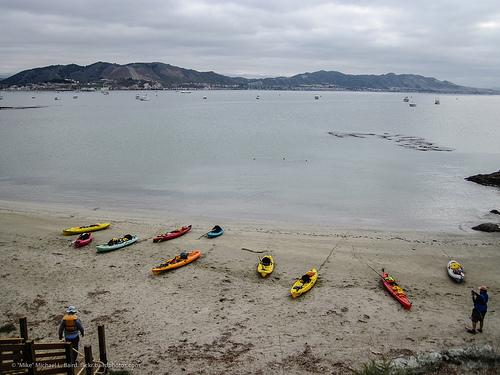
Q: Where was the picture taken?
A: By a body of water.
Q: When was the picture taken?
A: During day hours.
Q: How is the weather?
A: Cloudy.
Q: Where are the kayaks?
A: On the beach.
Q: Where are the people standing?
A: On the sand.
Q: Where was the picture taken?
A: On a beach.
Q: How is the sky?
A: Overcast.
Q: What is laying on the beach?
A: Kayaks.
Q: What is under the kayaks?
A: Sand.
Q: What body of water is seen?
A: An ocean.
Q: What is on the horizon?
A: Mountains.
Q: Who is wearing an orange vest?
A: A man in the lower left corner.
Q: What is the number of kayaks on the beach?
A: Ten.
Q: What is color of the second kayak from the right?
A: Red.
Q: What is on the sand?
A: Kayaks.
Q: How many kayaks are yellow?
A: 3.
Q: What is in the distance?
A: Land.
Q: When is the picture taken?
A: Daytime.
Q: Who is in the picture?
A: Kayakers.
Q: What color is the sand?
A: Tan.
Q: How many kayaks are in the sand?
A: 10.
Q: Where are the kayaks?
A: On the sand.